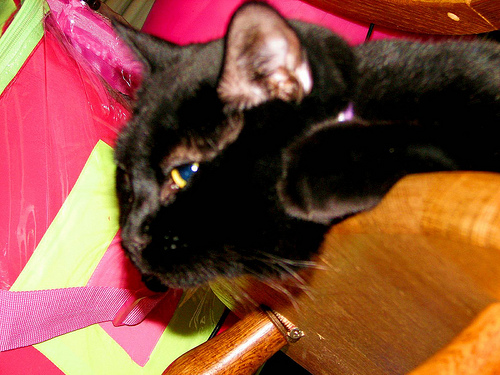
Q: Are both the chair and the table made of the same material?
A: Yes, both the chair and the table are made of wood.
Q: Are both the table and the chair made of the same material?
A: Yes, both the table and the chair are made of wood.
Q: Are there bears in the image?
A: No, there are no bears.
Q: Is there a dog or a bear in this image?
A: No, there are no bears or dogs.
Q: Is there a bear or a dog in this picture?
A: No, there are no bears or dogs.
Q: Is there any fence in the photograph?
A: No, there are no fences.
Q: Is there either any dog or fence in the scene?
A: No, there are no fences or dogs.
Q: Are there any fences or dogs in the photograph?
A: No, there are no fences or dogs.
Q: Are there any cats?
A: Yes, there is a cat.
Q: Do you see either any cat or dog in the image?
A: Yes, there is a cat.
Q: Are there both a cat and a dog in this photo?
A: No, there is a cat but no dogs.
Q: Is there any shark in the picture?
A: No, there are no sharks.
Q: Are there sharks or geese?
A: No, there are no sharks or geese.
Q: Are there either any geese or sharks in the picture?
A: No, there are no sharks or geese.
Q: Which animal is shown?
A: The animal is a cat.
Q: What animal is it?
A: The animal is a cat.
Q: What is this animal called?
A: This is a cat.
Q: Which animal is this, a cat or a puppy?
A: This is a cat.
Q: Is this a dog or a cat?
A: This is a cat.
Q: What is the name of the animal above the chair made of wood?
A: The animal is a cat.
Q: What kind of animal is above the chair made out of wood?
A: The animal is a cat.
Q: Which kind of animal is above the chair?
A: The animal is a cat.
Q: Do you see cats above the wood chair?
A: Yes, there is a cat above the chair.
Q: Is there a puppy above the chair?
A: No, there is a cat above the chair.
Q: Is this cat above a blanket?
A: No, the cat is above the chair.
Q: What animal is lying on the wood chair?
A: The cat is lying on the chair.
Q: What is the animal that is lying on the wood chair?
A: The animal is a cat.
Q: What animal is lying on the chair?
A: The animal is a cat.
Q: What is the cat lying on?
A: The cat is lying on the chair.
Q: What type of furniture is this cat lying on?
A: The cat is lying on the chair.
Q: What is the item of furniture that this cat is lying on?
A: The piece of furniture is a chair.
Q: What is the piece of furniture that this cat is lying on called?
A: The piece of furniture is a chair.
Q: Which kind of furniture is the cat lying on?
A: The cat is lying on the chair.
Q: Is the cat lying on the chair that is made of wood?
A: Yes, the cat is lying on the chair.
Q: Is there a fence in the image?
A: No, there are no fences.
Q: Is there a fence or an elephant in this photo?
A: No, there are no fences or elephants.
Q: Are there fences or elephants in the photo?
A: No, there are no fences or elephants.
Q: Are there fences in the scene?
A: No, there are no fences.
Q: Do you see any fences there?
A: No, there are no fences.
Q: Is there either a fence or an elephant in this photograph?
A: No, there are no fences or elephants.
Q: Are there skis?
A: No, there are no skis.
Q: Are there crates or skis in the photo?
A: No, there are no skis or crates.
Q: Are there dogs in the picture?
A: No, there are no dogs.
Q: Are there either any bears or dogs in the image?
A: No, there are no dogs or bears.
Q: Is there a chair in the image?
A: Yes, there is a chair.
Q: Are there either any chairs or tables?
A: Yes, there is a chair.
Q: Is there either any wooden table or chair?
A: Yes, there is a wood chair.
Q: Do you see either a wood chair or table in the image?
A: Yes, there is a wood chair.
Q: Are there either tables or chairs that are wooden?
A: Yes, the chair is wooden.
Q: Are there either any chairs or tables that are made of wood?
A: Yes, the chair is made of wood.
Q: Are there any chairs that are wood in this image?
A: Yes, there is a wood chair.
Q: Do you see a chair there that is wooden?
A: Yes, there is a chair that is wooden.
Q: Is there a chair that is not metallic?
A: Yes, there is a wooden chair.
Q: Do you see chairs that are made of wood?
A: Yes, there is a chair that is made of wood.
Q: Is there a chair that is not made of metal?
A: Yes, there is a chair that is made of wood.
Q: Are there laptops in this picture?
A: No, there are no laptops.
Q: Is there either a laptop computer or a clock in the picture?
A: No, there are no laptops or clocks.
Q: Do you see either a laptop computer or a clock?
A: No, there are no laptops or clocks.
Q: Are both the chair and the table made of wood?
A: Yes, both the chair and the table are made of wood.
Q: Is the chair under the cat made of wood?
A: Yes, the chair is made of wood.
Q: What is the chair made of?
A: The chair is made of wood.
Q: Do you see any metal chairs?
A: No, there is a chair but it is made of wood.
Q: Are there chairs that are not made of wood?
A: No, there is a chair but it is made of wood.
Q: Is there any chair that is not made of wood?
A: No, there is a chair but it is made of wood.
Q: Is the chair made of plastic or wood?
A: The chair is made of wood.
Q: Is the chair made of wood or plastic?
A: The chair is made of wood.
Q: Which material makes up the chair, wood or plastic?
A: The chair is made of wood.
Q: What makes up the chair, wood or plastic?
A: The chair is made of wood.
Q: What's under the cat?
A: The chair is under the cat.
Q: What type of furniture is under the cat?
A: The piece of furniture is a chair.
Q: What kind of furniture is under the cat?
A: The piece of furniture is a chair.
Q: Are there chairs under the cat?
A: Yes, there is a chair under the cat.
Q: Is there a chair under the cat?
A: Yes, there is a chair under the cat.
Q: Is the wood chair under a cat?
A: Yes, the chair is under a cat.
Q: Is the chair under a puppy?
A: No, the chair is under a cat.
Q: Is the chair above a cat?
A: No, the chair is under a cat.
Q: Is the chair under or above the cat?
A: The chair is under the cat.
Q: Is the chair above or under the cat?
A: The chair is under the cat.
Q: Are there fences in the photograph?
A: No, there are no fences.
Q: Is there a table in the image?
A: Yes, there is a table.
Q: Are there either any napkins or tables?
A: Yes, there is a table.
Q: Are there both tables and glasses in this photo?
A: No, there is a table but no glasses.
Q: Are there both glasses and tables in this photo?
A: No, there is a table but no glasses.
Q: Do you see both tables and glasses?
A: No, there is a table but no glasses.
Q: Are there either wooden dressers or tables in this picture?
A: Yes, there is a wood table.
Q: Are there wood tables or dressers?
A: Yes, there is a wood table.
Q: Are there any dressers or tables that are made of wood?
A: Yes, the table is made of wood.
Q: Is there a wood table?
A: Yes, there is a table that is made of wood.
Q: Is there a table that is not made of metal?
A: Yes, there is a table that is made of wood.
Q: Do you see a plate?
A: No, there are no plates.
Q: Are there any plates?
A: No, there are no plates.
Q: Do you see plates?
A: No, there are no plates.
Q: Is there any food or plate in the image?
A: No, there are no plates or food.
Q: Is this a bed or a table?
A: This is a table.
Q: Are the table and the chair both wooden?
A: Yes, both the table and the chair are wooden.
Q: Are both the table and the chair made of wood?
A: Yes, both the table and the chair are made of wood.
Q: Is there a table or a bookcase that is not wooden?
A: No, there is a table but it is wooden.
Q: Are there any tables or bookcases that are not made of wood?
A: No, there is a table but it is made of wood.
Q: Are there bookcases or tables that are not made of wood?
A: No, there is a table but it is made of wood.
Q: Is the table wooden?
A: Yes, the table is wooden.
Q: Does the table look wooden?
A: Yes, the table is wooden.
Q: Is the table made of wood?
A: Yes, the table is made of wood.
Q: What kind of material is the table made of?
A: The table is made of wood.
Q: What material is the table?
A: The table is made of wood.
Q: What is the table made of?
A: The table is made of wood.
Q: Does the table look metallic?
A: No, the table is wooden.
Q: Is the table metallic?
A: No, the table is wooden.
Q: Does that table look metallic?
A: No, the table is wooden.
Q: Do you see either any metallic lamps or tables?
A: No, there is a table but it is wooden.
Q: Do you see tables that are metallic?
A: No, there is a table but it is wooden.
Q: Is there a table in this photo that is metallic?
A: No, there is a table but it is wooden.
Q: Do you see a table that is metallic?
A: No, there is a table but it is wooden.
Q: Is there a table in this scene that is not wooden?
A: No, there is a table but it is wooden.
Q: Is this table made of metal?
A: No, the table is made of wood.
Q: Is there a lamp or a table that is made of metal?
A: No, there is a table but it is made of wood.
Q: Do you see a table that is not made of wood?
A: No, there is a table but it is made of wood.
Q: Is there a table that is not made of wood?
A: No, there is a table but it is made of wood.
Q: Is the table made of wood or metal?
A: The table is made of wood.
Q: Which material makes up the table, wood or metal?
A: The table is made of wood.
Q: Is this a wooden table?
A: Yes, this is a wooden table.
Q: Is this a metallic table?
A: No, this is a wooden table.